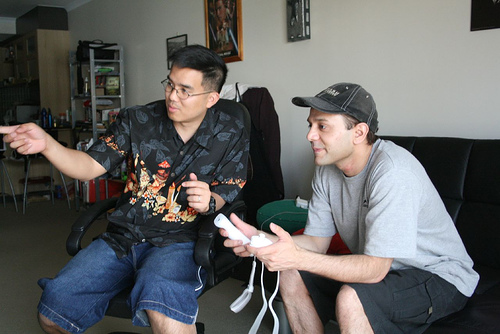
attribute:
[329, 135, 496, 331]
sofa — green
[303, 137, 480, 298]
shirt — gray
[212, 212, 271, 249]
controller — white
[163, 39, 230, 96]
hair — black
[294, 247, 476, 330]
shorts — black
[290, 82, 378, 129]
hat — black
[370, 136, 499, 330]
couch — black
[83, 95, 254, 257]
shirt — black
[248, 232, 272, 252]
game controller — white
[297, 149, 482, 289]
t-shirt — gray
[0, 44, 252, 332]
man — sitting, playing video game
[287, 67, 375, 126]
cap — black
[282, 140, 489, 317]
shirt — grey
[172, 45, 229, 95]
hair — black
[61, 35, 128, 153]
shelf — metal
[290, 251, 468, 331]
shorts — dark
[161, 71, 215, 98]
glasses — rimless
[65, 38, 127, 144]
shelf — gray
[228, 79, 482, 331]
man — sitting, playing video game